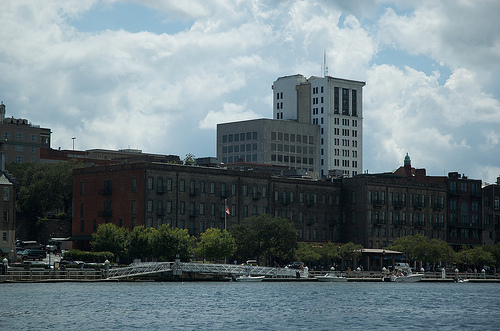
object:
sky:
[199, 1, 264, 76]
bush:
[232, 214, 298, 268]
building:
[213, 118, 322, 176]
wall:
[296, 105, 311, 119]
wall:
[289, 100, 311, 104]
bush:
[93, 222, 132, 266]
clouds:
[367, 59, 484, 168]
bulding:
[71, 162, 339, 233]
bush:
[194, 224, 240, 263]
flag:
[217, 195, 235, 218]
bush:
[121, 221, 198, 263]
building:
[271, 50, 364, 165]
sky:
[3, 2, 170, 82]